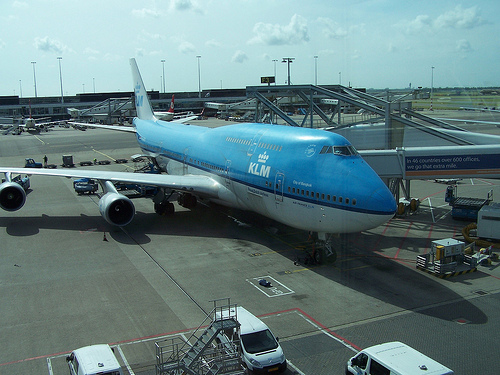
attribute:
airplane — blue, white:
[1, 56, 401, 268]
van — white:
[212, 306, 283, 370]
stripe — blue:
[135, 140, 400, 217]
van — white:
[345, 336, 457, 373]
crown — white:
[256, 150, 269, 164]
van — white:
[63, 342, 128, 373]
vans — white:
[193, 293, 449, 372]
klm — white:
[247, 160, 270, 178]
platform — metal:
[153, 299, 260, 374]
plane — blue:
[5, 55, 497, 254]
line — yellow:
[280, 252, 370, 274]